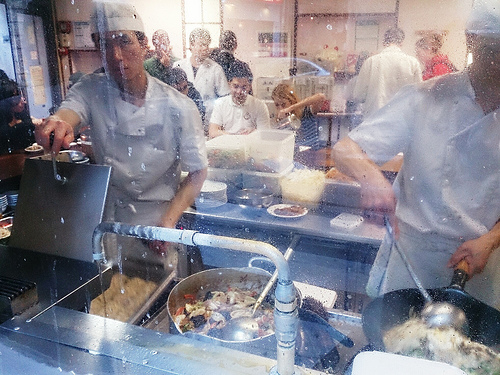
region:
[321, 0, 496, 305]
Man in white apron is cooking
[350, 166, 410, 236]
Hand holding large spoon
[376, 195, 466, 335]
Large spoon on black pan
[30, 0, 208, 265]
Man in white apron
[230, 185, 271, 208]
Stainless steel mixing bowl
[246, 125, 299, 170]
White container on top of container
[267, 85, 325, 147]
Woman in striped shirt pouring pitcher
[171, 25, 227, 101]
Man in white shirt is standing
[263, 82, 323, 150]
Woman has red hair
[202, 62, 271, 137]
Man in white shirt next to woman in striped shirt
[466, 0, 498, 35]
A white hat of a chef.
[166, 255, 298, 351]
A silver pot.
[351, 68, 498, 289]
White uniform of a chef.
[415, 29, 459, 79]
A woman with a red cloth.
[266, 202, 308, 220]
A white plate on a counter.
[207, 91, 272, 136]
A white polo shirt.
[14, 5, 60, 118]
A glass door.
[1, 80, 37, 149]
A person with a black hair.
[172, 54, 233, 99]
A person in a white shirt.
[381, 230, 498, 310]
A white epron on a chef.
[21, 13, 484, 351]
a busy cafeteria area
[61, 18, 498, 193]
these men are serving food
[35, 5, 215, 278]
he is busy working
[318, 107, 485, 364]
this guy is stirring some food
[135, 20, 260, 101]
these people are ordering food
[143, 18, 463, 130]
this is a restuarant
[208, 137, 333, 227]
lots of food items on the counter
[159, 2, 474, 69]
the dining area behind the guests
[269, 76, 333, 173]
this person is pouring something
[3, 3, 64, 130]
a doorway to the restuarant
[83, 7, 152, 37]
The hat is white.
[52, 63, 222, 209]
The shirt is white.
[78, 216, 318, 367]
The faucet is grey.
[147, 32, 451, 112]
The people are waiting.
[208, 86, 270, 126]
He is wearing a white shirt.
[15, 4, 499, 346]
The men are cooking.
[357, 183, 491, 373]
He has a pan.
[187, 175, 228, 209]
a stack of plates on the table.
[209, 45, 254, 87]
He is wearing a black shirt.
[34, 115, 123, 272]
He is lifting the lid.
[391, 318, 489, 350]
food is in the pan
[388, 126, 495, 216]
the shirt is white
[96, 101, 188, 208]
the shirt is white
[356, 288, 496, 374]
the pan is on the cooker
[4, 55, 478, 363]
the kitchen is a commercial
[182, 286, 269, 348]
the pot is halffull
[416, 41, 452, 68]
woman is in the background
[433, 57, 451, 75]
the top is red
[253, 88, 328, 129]
the girl is holding a kettle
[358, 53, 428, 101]
the shirt is white